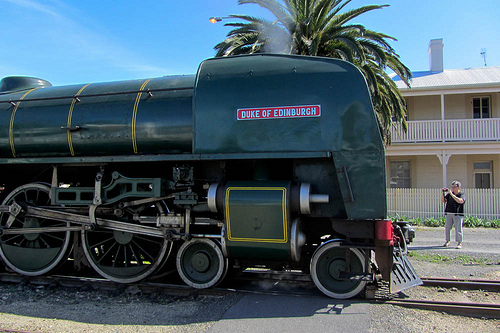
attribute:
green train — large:
[0, 50, 430, 302]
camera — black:
[430, 181, 452, 198]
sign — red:
[235, 108, 331, 120]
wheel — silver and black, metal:
[303, 233, 369, 302]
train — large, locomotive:
[0, 53, 422, 300]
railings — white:
[391, 181, 498, 218]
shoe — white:
[455, 235, 462, 247]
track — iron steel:
[402, 275, 499, 317]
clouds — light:
[80, 25, 142, 63]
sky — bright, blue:
[123, 8, 176, 49]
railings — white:
[389, 184, 499, 227]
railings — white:
[388, 115, 498, 144]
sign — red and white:
[237, 104, 321, 119]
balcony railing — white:
[405, 116, 498, 143]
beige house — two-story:
[381, 46, 499, 229]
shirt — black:
[443, 193, 463, 213]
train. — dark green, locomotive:
[35, 47, 435, 331]